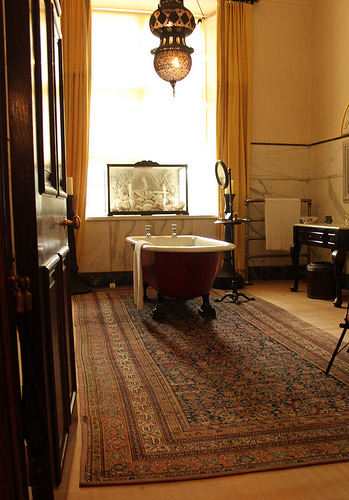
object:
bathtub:
[125, 234, 236, 319]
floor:
[66, 276, 349, 498]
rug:
[73, 278, 348, 486]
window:
[79, 13, 216, 215]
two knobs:
[143, 222, 178, 237]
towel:
[131, 239, 151, 309]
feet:
[150, 299, 168, 320]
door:
[5, 0, 82, 498]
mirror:
[215, 160, 228, 188]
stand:
[213, 193, 256, 303]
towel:
[264, 196, 302, 251]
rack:
[243, 196, 312, 284]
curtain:
[58, 0, 91, 274]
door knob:
[62, 215, 82, 231]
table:
[288, 204, 348, 306]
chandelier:
[149, 1, 197, 100]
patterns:
[79, 378, 250, 403]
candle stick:
[222, 192, 236, 216]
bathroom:
[0, 0, 348, 498]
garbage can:
[304, 259, 335, 299]